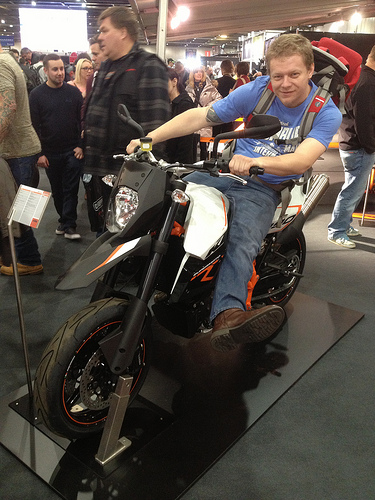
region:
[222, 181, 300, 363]
the leg of a man ridding a motor bike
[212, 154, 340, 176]
the hand of a man riding a motor bike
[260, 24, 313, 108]
the head of a man on a motor bike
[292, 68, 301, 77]
the eye of a man on the motor bike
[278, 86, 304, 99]
the mouth of a man on a motor bike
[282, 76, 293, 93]
the nose of a man on a motor bike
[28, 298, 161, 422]
the wheel of the motor bike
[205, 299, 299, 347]
the shoe of a man riding a motor bike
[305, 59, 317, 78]
the ear of a man riding a motor bike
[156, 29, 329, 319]
a man on a motor bike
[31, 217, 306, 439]
black motorcycle sitting on the floor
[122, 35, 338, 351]
man sitting on the black motorcycle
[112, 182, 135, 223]
headlight of the motorcycle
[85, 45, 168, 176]
black and gray top the man is wearing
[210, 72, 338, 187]
blue shirt man is wearing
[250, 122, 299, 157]
white print on the blue shirt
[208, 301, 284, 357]
brown left shoe worn by the man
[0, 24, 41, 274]
man walking around the floor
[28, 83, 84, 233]
black outfit man is wearing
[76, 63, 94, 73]
eyeglasses the woman is wearing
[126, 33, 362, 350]
A boy with a red backpack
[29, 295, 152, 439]
The front tire of a motorcycle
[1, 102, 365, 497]
A motorcycle display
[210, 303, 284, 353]
A brown leather boot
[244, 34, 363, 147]
A red, black, and grey backpack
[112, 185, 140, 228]
A headlight on a motorcycle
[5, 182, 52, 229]
An informational sign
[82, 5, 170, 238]
A man in a striped shirt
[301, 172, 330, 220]
A silver tail pipe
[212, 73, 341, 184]
A blue shirt with white writing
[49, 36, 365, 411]
man on top of motorcycle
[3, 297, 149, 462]
black front wheel of motorcycle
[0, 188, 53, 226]
white sign in front of cycle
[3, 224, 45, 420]
black pole for sign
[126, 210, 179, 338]
black frame of bike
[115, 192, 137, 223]
front light of motorcycle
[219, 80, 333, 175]
blue shirt on man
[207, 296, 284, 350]
brown shoes on feet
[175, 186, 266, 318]
blue jeans on man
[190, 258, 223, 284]
orange and black bike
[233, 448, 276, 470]
Small part of a black floor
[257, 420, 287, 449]
Small part of a black floor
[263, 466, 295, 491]
Small part of a black floor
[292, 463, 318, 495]
Small part of a black floor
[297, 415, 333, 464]
Small part of a black floor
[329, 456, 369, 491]
Small part of a black floor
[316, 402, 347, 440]
Small part of a black floor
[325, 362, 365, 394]
Small part of a black floor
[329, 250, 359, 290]
Small part of a black floor